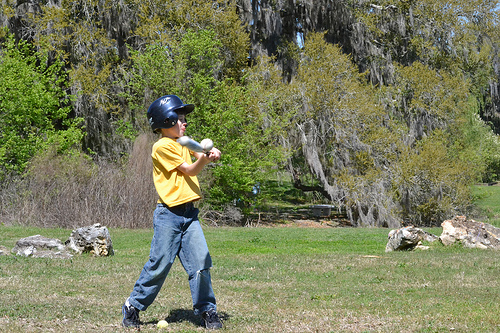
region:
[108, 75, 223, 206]
boy holding baseball bat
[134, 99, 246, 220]
boy hitting white baseball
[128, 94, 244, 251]
boy wearing yellow shirt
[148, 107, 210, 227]
yellow shirt on boy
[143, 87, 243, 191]
black helmet on boy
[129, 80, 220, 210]
boy wearing black helmet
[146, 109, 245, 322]
boy wearing blue jeans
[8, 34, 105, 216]
green trees behind boy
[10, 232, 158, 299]
large rock behind boy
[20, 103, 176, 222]
tall grass behind boy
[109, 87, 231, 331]
child swinging a baseball bat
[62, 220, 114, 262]
large boulder in the ground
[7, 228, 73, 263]
large boulder in the ground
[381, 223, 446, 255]
large boulder in the ground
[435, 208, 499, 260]
large boulder in the ground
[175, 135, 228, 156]
silver metal baseball bat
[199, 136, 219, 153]
white baseball in the air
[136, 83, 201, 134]
child sized black helmet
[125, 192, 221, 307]
pair of blue jeans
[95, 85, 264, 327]
child wearing yellow shirt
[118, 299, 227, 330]
Black tennis shoes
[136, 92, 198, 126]
A black baseball helmet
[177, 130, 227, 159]
The bat hitting the ball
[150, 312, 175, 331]
A spare ball sitting on the ground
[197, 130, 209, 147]
A white baseball mid air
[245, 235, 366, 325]
A sparse grassy area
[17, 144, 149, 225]
Dead trees beyond the field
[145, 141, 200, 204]
A yellow t shirt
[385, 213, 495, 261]
A grey rocky area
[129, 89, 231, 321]
A boy playing baseball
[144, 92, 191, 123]
The helmet on the kid's head.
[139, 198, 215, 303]
The blue jeans the kid is wearing.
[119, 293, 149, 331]
The kid's left sneaker.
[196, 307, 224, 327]
The kid's right sneaker.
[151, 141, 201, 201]
The yellow shirt the kid is wearing.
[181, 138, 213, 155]
The baseball bat in the kid's hands.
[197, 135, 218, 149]
The baseball the kid is hitting.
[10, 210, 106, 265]
The rocks on the left.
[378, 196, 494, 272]
The rocks on the right.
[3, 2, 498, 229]
The trees in the background.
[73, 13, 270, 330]
a boy standing outside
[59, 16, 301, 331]
a boy standing on the grass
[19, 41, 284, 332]
a boy standing in the field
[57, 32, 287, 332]
a boy swing a bat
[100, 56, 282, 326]
a boy playing bat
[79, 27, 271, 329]
a boy wearing a helmet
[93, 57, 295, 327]
a boy wearing a black helmet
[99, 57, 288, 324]
a boy wearing a shirt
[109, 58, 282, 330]
a boy waering a yellow shirt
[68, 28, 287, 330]
a boy wearing pants